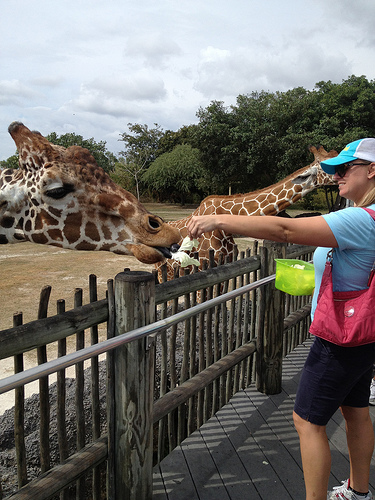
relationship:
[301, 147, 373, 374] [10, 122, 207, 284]
woman petting giraffe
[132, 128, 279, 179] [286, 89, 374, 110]
forest of trees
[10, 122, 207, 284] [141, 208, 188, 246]
giraffe has nose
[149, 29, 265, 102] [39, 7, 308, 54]
cloud in sky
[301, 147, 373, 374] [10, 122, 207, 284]
woman feeding giraffe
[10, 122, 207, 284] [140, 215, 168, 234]
giraffe has big nostril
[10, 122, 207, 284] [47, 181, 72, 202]
giraffe has dark eye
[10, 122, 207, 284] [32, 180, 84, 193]
giraffe has long eyelashes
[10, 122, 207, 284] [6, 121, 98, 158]
giraffe has horns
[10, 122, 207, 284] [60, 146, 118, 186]
giraffe has bumps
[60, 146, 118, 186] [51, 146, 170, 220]
bumps on forehead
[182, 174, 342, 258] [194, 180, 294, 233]
giraffe has crooked neck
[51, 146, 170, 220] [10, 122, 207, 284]
forehead of giraffe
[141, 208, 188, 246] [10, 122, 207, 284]
nose of giraffe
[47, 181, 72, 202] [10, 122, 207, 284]
dark eye of giraffe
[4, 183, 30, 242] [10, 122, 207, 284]
ear of giraffe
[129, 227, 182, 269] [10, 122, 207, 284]
mouth of giraffe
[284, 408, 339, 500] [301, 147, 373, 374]
leg of woman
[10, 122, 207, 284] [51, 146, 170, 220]
giraffe has forehead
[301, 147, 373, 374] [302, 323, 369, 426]
woman in shorts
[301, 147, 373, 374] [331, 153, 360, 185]
woman in sunglasses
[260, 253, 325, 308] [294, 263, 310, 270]
object has giraffe food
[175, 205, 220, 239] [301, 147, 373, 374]
hand of woman